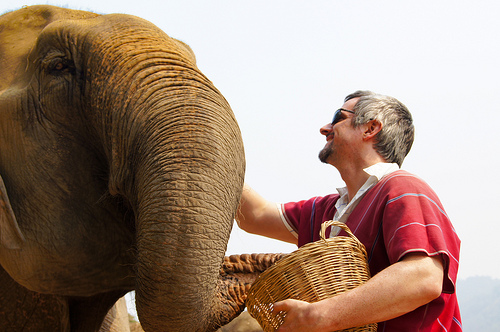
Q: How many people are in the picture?
A: One.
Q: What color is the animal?
A: Brown.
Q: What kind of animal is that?
A: Elephant.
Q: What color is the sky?
A: White.